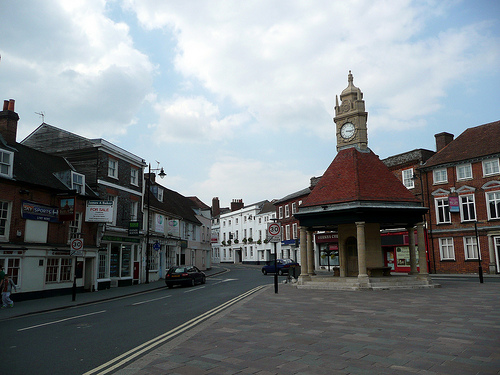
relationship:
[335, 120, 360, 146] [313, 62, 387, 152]
clock on tower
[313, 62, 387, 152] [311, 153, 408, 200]
tower on roof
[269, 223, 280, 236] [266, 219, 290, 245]
circle on sign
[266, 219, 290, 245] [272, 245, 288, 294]
sign on pole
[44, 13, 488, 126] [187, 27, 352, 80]
sky has clouds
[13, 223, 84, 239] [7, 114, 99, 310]
board on building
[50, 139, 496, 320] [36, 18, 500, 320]
city in photo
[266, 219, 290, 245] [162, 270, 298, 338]
sign on street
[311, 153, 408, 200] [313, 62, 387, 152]
roof on tower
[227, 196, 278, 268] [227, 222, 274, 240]
building has windows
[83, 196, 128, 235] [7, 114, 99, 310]
sign on building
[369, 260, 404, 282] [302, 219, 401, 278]
bench in area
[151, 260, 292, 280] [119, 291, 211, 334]
cars on road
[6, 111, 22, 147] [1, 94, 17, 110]
chimney has pipes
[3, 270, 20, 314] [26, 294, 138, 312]
man on sidewalk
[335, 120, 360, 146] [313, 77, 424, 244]
clock on building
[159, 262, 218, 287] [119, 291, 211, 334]
car on road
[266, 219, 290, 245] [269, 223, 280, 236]
sign has circle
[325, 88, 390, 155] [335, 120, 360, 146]
gazebo has clock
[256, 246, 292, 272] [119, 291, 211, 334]
car on road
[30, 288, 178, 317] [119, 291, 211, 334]
lines on road